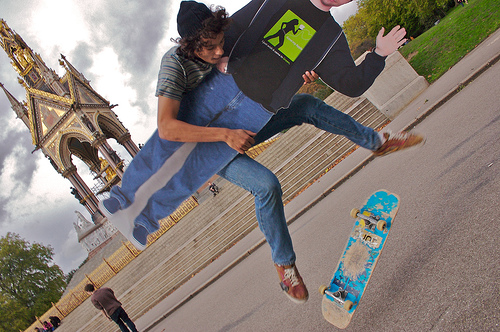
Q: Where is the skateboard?
A: In the air.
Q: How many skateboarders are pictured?
A: One.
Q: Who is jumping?
A: The skateboarder.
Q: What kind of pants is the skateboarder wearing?
A: Jeans.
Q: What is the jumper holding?
A: A life size cutout.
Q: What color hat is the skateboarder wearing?
A: Black.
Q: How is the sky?
A: Cloudy.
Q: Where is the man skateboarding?
A: On pavement.